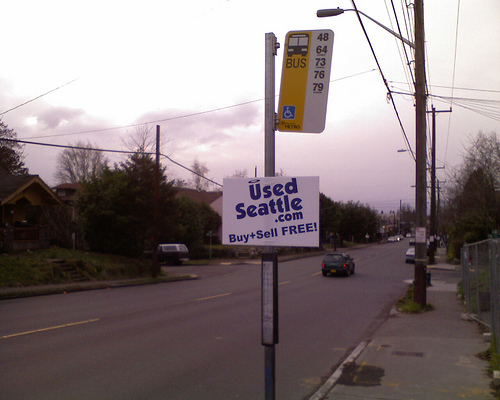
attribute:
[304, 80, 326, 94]
79 — black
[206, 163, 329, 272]
sign — white, red, yellow, rectangular, blue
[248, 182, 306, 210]
letters — blue, red, saying free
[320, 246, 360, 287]
car — driving, parked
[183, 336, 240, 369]
street — gray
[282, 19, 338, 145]
sign — bus stop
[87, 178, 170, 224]
tree — green, leafy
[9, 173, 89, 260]
house — yellow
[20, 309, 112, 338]
line — yellow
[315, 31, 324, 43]
4 — on sign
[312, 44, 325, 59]
6 — on sign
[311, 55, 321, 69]
7 — on sign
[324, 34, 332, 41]
8 — on sign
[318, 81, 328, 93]
9 — on sign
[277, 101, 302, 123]
handicap placard — on sign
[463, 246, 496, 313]
fence — silver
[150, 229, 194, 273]
vehicle — parked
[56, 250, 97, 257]
grass — green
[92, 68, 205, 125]
sky — cloudy, white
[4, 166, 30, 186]
roof — brown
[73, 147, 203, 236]
trees — bare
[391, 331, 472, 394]
sidewalk — empty, pavement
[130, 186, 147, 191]
leaves — green